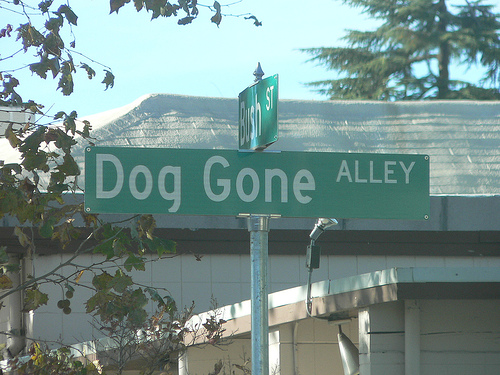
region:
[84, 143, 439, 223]
Dog Gone Alley Street sign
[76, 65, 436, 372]
green and white street signs on metal pole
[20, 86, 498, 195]
building roof with gray asphalt shingles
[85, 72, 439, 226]
Green and white metal street signs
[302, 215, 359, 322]
exterior lighting floodlamp and wiring conduit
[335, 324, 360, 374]
exterior light fixture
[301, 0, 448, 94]
evergreen tree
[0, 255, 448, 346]
gray cement block wall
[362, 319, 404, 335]
wiring conduit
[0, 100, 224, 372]
foliage of deciduous tree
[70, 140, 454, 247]
Green and white road sign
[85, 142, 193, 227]
the word dog on a sign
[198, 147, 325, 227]
the word gone on a sign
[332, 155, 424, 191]
the word alley on a sign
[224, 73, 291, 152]
Bush st road sign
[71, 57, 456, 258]
Two green road signs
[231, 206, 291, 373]
Metal pole holding street signs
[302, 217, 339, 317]
Security light on a house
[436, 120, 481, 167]
White roof of a house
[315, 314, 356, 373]
Metal light attached to a roof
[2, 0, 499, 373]
a scene outside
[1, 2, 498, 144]
a blue sky with no clouds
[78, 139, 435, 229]
a green street sign DOG GONE ALLEY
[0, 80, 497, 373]
a white building in background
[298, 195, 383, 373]
a silver light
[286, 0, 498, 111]
a green tree in the distance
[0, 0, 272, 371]
some branches of a tree in the forefront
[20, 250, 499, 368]
a white brick wall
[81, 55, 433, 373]
a street sign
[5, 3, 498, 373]
image of a street corner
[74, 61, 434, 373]
green street signs on grey pole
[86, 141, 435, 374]
green and white street sign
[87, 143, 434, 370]
green rectangle street sign with white writing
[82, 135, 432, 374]
street sign that says Dog Gone Alley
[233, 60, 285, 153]
small street sign indicating Bush street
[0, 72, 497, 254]
light color rooftop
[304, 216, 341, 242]
unlit light pointing up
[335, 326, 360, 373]
silver light lamp facing down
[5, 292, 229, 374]
small tree with mostly bare branches and leaves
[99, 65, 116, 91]
green leaf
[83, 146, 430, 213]
A rectangular sign.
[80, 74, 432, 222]
One sign on top of another.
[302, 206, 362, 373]
Lights on the side of a building.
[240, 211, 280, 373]
A metal sign post.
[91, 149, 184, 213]
The word Dog in white letters.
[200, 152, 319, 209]
The word Gone in white letters.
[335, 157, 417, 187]
The word Alley in white letters.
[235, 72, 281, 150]
A sign that says Bush St.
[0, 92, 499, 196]
A view of a rooftop.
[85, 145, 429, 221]
A green sign with white letters.